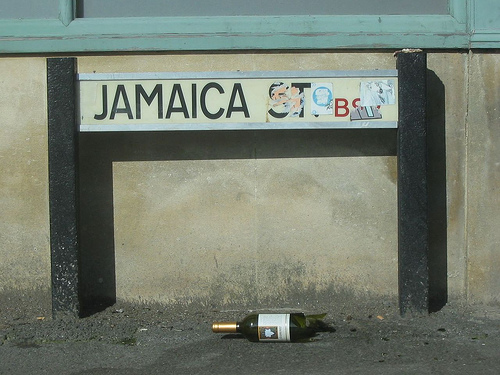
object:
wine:
[211, 309, 308, 338]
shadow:
[155, 324, 356, 371]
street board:
[35, 50, 445, 312]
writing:
[71, 79, 400, 124]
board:
[78, 73, 399, 128]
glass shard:
[291, 307, 335, 341]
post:
[40, 54, 82, 316]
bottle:
[192, 297, 359, 335]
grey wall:
[111, 142, 397, 317]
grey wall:
[429, 52, 498, 301]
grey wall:
[1, 58, 48, 310]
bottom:
[291, 312, 308, 340]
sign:
[73, 56, 403, 144]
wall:
[2, 60, 491, 297]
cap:
[209, 317, 239, 337]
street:
[14, 289, 498, 369]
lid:
[211, 322, 218, 332]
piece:
[305, 310, 328, 320]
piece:
[304, 319, 319, 334]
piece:
[301, 330, 320, 340]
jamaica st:
[91, 80, 317, 119]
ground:
[0, 308, 500, 373]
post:
[395, 46, 431, 316]